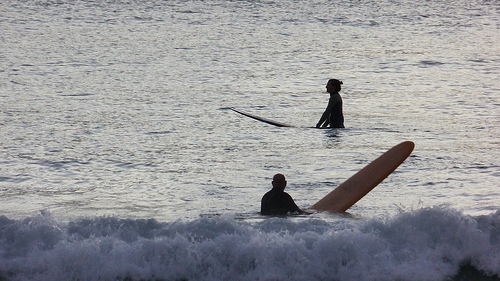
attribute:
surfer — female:
[313, 79, 349, 134]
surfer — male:
[252, 172, 312, 229]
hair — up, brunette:
[320, 70, 351, 95]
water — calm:
[53, 45, 185, 115]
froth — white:
[91, 247, 121, 271]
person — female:
[313, 77, 350, 131]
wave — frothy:
[10, 209, 497, 271]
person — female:
[315, 70, 344, 126]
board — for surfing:
[224, 98, 291, 133]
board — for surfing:
[311, 139, 415, 212]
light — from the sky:
[343, 15, 497, 56]